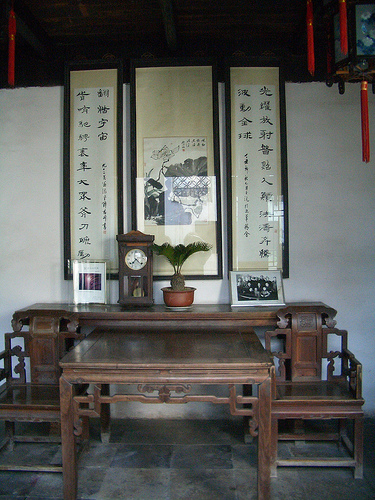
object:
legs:
[58, 376, 271, 500]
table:
[57, 322, 277, 499]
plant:
[154, 241, 213, 312]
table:
[13, 302, 336, 339]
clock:
[115, 228, 157, 307]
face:
[123, 248, 148, 272]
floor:
[0, 415, 374, 499]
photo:
[229, 266, 284, 308]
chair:
[0, 303, 365, 482]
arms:
[352, 356, 362, 398]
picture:
[70, 260, 106, 308]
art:
[58, 60, 287, 281]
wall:
[0, 76, 374, 418]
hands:
[126, 258, 144, 268]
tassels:
[7, 0, 372, 165]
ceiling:
[0, 1, 374, 89]